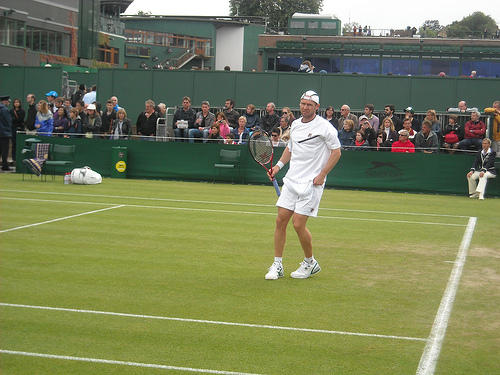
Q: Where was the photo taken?
A: Court.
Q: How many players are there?
A: One.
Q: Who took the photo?
A: Friend.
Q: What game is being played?
A: Tennis.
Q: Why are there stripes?
A: Court markers.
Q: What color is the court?
A: Green.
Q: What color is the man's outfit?
A: White.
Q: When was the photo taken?
A: During game.